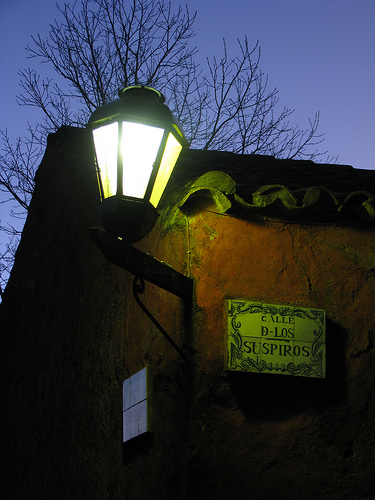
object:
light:
[86, 84, 189, 241]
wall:
[0, 124, 188, 500]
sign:
[225, 298, 324, 378]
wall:
[185, 197, 374, 500]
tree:
[0, 0, 338, 303]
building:
[0, 125, 375, 500]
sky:
[0, 0, 375, 306]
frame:
[86, 82, 187, 238]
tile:
[294, 340, 327, 381]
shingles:
[177, 185, 231, 213]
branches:
[15, 68, 59, 130]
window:
[123, 397, 147, 443]